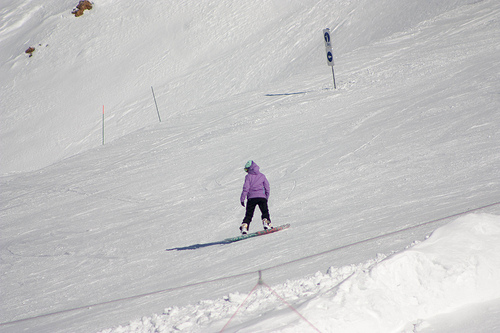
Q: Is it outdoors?
A: Yes, it is outdoors.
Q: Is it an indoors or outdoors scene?
A: It is outdoors.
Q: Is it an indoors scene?
A: No, it is outdoors.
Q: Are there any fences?
A: No, there are no fences.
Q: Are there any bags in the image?
A: No, there are no bags.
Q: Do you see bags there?
A: No, there are no bags.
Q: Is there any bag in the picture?
A: No, there are no bags.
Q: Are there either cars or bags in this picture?
A: No, there are no bags or cars.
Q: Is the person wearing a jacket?
A: Yes, the person is wearing a jacket.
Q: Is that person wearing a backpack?
A: No, the person is wearing a jacket.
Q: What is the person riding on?
A: The person is riding on the snowboard.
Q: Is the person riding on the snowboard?
A: Yes, the person is riding on the snowboard.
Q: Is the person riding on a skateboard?
A: No, the person is riding on the snowboard.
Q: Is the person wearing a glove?
A: Yes, the person is wearing a glove.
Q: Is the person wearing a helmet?
A: No, the person is wearing a glove.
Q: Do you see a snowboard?
A: Yes, there is a snowboard.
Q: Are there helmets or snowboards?
A: Yes, there is a snowboard.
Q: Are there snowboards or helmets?
A: Yes, there is a snowboard.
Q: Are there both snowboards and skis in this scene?
A: No, there is a snowboard but no skis.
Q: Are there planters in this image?
A: No, there are no planters.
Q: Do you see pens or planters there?
A: No, there are no planters or pens.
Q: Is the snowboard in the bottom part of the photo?
A: Yes, the snowboard is in the bottom of the image.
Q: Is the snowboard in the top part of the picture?
A: No, the snowboard is in the bottom of the image.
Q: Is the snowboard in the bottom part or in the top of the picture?
A: The snowboard is in the bottom of the image.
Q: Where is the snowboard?
A: The snowboard is on the ground.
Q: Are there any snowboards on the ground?
A: Yes, there is a snowboard on the ground.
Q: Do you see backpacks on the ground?
A: No, there is a snowboard on the ground.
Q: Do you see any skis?
A: No, there are no skis.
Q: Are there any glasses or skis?
A: No, there are no skis or glasses.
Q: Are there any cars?
A: No, there are no cars.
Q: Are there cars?
A: No, there are no cars.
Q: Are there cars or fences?
A: No, there are no cars or fences.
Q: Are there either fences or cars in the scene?
A: No, there are no cars or fences.